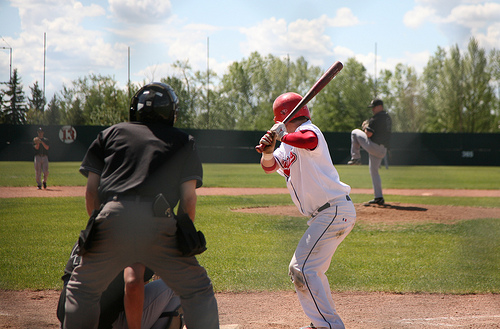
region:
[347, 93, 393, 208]
A pitcher getting ready to throw the ball.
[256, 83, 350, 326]
A ball player up to bat.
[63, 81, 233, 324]
An umpire for a baseball game.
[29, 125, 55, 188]
A ball player waiting for a play.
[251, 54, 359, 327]
A boy getting ready to swing a bat.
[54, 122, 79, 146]
A baseball logo on the wall of a ballpark.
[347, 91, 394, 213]
A man pitching from the pitchers mound.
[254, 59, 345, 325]
A man holding a baseball bat.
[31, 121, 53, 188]
A ball player in the outfield.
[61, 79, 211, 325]
The backside of an umpire.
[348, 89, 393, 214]
Pitcher is preparing to throw the ball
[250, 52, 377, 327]
Baseball player preparing to swing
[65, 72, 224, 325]
Umpire judging the pitch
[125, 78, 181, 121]
Umpire wearing a black helmet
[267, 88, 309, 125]
Player wearing a red helmet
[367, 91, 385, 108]
Pitcher wearing a black hat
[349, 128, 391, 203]
Pitcher wearing grey pants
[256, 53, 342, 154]
Baseball bat made of wood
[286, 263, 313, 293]
Grass stains on white pants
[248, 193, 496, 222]
Pitcher mound of dirt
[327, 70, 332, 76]
A man swinging a bat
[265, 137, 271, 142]
Fingers wrapped around a bat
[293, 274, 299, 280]
Trousers soiled around the knee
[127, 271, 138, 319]
Arm seen through the legs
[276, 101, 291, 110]
A protective hat on the head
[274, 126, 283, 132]
Hand with glove holding a bat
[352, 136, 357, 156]
Leg up preparing to pitch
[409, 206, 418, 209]
Shadow on the ground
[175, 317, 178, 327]
Protection around the shin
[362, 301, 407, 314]
A bare patch on the ground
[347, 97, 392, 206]
A pitcher with his leg up, ready to throw a baseball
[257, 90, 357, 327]
A batter anticipating a ball being pitched to him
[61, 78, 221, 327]
An umpire dressed in grey, slightly bent at the knees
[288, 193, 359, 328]
Baseball pants with dirt stains on the knee and rear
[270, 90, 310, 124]
Red baseball safety helmet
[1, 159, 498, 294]
Green grass, recently mowed, on a ball field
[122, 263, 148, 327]
Bare arm of the catcher, bent slightly at the elbow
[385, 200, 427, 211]
Shadow of the pitcher, on the pitcher's mound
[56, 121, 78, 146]
Number 13 on a baseball shaped sign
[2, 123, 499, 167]
Tall green fence in the outfield of the baseball diamond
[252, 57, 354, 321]
batter in white and red uniform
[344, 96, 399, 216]
pitcher in gray and black uniform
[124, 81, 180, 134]
shiny black plastic helmet on umpire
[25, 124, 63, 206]
player in the dirt of the field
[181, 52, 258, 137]
tall trees growing behind the fence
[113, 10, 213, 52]
white clouds in light blue sky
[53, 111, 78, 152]
number thirteen on a baseball shaped sign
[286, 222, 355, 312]
brown dirt on batter's white pants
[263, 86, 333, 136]
red plastic helmet on batter's head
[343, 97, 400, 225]
pitcher getting ready to throw ball